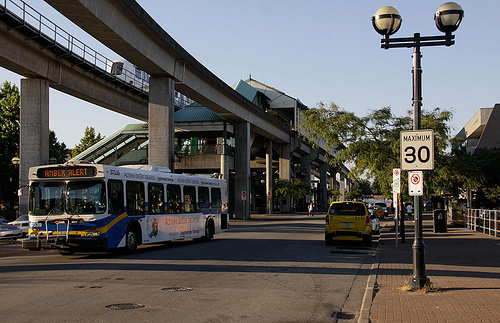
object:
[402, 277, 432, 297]
grass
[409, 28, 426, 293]
post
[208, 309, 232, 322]
stain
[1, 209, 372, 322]
road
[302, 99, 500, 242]
tree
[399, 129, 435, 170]
sign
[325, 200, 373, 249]
cab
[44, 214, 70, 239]
bike rack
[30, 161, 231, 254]
bus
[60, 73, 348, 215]
building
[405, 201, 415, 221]
man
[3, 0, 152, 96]
fence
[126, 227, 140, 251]
wheel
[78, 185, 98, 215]
driver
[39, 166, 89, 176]
letters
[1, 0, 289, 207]
bridge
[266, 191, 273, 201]
sign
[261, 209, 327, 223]
shadow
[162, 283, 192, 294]
man hole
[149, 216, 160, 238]
logo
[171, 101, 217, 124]
roof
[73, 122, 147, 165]
steps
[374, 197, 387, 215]
van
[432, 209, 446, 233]
trash can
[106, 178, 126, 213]
window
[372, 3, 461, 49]
light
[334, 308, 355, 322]
drain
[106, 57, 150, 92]
train